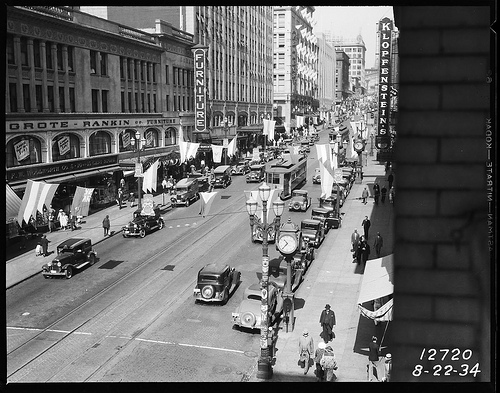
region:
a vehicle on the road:
[188, 251, 240, 311]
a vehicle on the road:
[41, 236, 103, 291]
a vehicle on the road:
[122, 203, 169, 241]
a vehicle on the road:
[240, 279, 288, 344]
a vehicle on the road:
[256, 250, 311, 302]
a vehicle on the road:
[288, 215, 330, 250]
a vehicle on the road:
[281, 187, 312, 217]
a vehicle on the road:
[168, 172, 198, 212]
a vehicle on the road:
[213, 152, 233, 189]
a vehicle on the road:
[247, 158, 264, 183]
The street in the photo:
[6, 110, 361, 392]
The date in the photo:
[402, 337, 487, 383]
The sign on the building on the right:
[369, 8, 399, 154]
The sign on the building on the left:
[190, 42, 212, 135]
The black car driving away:
[187, 257, 242, 303]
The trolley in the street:
[258, 145, 313, 202]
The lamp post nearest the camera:
[245, 176, 285, 377]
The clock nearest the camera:
[275, 216, 302, 331]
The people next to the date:
[290, 300, 381, 380]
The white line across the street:
[5, 323, 251, 353]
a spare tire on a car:
[197, 282, 214, 298]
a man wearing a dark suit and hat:
[314, 303, 332, 344]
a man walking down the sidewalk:
[291, 328, 313, 372]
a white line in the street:
[141, 334, 200, 349]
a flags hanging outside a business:
[26, 176, 64, 217]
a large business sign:
[189, 46, 229, 133]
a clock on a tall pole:
[275, 220, 308, 325]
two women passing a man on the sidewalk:
[316, 345, 344, 385]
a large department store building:
[0, 20, 171, 174]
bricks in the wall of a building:
[410, 145, 465, 319]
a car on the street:
[36, 234, 98, 284]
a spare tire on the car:
[200, 282, 219, 302]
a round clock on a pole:
[276, 233, 300, 257]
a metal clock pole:
[279, 254, 296, 337]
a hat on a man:
[320, 302, 339, 312]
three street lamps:
[239, 179, 288, 245]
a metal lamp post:
[250, 231, 274, 382]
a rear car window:
[199, 273, 219, 284]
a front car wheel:
[63, 264, 75, 281]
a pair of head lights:
[44, 259, 64, 271]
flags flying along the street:
[125, 80, 333, 162]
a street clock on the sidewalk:
[272, 224, 313, 315]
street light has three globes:
[251, 179, 286, 275]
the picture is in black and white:
[129, 107, 423, 309]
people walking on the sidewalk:
[303, 285, 352, 376]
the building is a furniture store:
[176, 41, 242, 154]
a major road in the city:
[118, 59, 420, 300]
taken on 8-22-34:
[414, 329, 498, 382]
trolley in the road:
[242, 133, 322, 204]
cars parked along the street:
[232, 169, 370, 304]